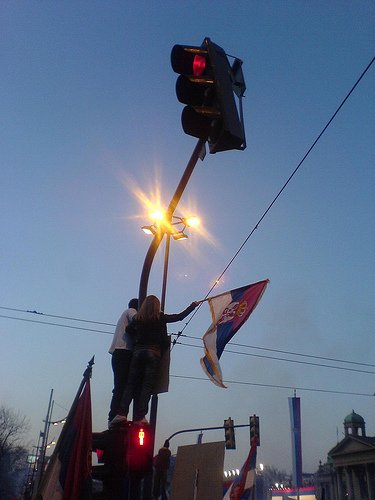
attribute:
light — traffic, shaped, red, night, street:
[156, 24, 270, 177]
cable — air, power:
[278, 93, 366, 233]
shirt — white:
[105, 304, 161, 358]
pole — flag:
[181, 250, 295, 393]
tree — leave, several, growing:
[2, 382, 38, 455]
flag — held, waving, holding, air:
[192, 243, 294, 392]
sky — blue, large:
[42, 77, 111, 173]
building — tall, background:
[258, 378, 328, 492]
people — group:
[56, 278, 221, 476]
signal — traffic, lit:
[140, 45, 267, 206]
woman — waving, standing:
[67, 239, 212, 433]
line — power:
[24, 291, 100, 341]